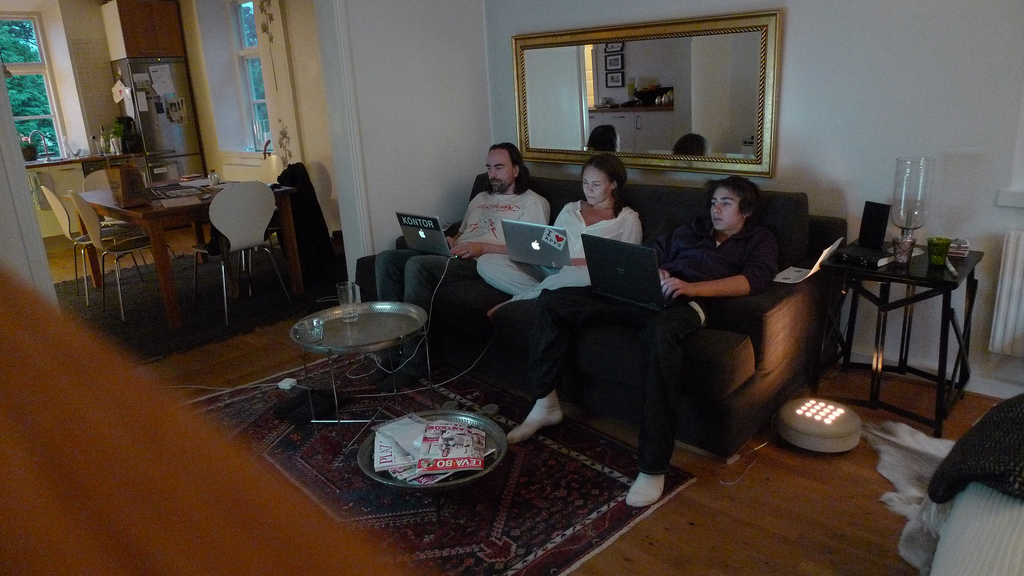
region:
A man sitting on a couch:
[370, 138, 547, 303]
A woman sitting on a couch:
[475, 149, 643, 314]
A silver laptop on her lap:
[503, 211, 576, 269]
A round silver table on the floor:
[282, 296, 437, 404]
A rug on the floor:
[182, 348, 699, 568]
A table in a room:
[810, 236, 979, 420]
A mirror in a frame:
[523, 34, 767, 159]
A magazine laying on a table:
[411, 418, 489, 473]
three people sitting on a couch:
[367, 133, 783, 511]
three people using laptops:
[373, 139, 779, 513]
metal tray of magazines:
[354, 405, 510, 495]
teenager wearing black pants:
[501, 174, 783, 510]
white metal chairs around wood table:
[33, 157, 309, 341]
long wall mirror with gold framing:
[506, 9, 782, 178]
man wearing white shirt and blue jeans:
[367, 138, 548, 395]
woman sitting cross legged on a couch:
[473, 149, 645, 318]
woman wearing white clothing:
[471, 145, 648, 320]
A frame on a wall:
[507, 12, 789, 181]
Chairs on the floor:
[38, 164, 168, 336]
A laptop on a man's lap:
[394, 206, 449, 260]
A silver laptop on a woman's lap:
[497, 212, 568, 271]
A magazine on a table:
[413, 398, 478, 478]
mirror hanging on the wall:
[497, 16, 810, 181]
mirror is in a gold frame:
[506, 11, 805, 177]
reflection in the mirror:
[516, 26, 769, 156]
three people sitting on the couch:
[345, 104, 845, 519]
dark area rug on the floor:
[185, 308, 698, 572]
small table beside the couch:
[824, 212, 983, 434]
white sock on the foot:
[623, 456, 674, 511]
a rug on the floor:
[167, 360, 654, 554]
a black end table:
[837, 233, 956, 427]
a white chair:
[199, 193, 283, 312]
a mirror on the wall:
[512, 28, 769, 161]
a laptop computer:
[566, 233, 683, 316]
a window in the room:
[0, 16, 74, 172]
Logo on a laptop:
[522, 233, 543, 254]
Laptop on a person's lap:
[580, 231, 673, 320]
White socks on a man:
[502, 390, 578, 451]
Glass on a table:
[326, 276, 371, 325]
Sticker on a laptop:
[394, 204, 449, 234]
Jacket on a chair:
[269, 156, 343, 306]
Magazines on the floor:
[375, 412, 490, 485]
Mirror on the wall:
[484, 13, 794, 175]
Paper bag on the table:
[92, 149, 157, 210]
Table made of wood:
[81, 172, 300, 255]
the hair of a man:
[479, 138, 527, 161]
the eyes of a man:
[479, 153, 508, 174]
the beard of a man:
[487, 166, 517, 196]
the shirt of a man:
[447, 182, 555, 244]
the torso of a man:
[466, 188, 521, 240]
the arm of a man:
[435, 239, 494, 258]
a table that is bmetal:
[295, 293, 416, 367]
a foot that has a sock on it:
[501, 379, 582, 449]